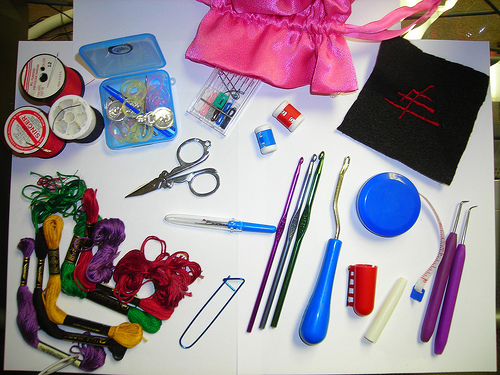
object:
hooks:
[420, 199, 478, 356]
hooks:
[246, 150, 326, 332]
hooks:
[297, 151, 351, 348]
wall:
[445, 77, 499, 114]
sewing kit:
[182, 60, 262, 140]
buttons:
[109, 92, 173, 142]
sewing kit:
[32, 13, 489, 361]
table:
[21, 32, 496, 317]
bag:
[336, 37, 491, 187]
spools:
[3, 50, 103, 162]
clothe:
[184, 2, 441, 95]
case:
[174, 55, 277, 144]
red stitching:
[390, 85, 438, 124]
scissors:
[127, 139, 222, 204]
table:
[459, 3, 498, 43]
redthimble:
[344, 262, 382, 314]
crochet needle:
[270, 151, 325, 328]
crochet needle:
[259, 153, 319, 328]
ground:
[405, 159, 444, 192]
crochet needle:
[252, 150, 319, 329]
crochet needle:
[241, 155, 305, 335]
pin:
[217, 67, 242, 102]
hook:
[299, 154, 351, 346]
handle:
[299, 238, 341, 344]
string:
[114, 230, 198, 317]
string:
[88, 215, 119, 283]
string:
[79, 187, 98, 289]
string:
[41, 212, 65, 325]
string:
[18, 237, 39, 340]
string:
[11, 173, 198, 373]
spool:
[48, 94, 105, 144]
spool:
[4, 106, 66, 158]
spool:
[19, 53, 85, 106]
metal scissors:
[123, 137, 221, 199]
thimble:
[346, 265, 377, 316]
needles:
[246, 149, 352, 344]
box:
[77, 33, 176, 150]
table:
[20, 5, 498, 373]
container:
[29, 31, 478, 372]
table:
[137, 81, 456, 364]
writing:
[375, 79, 448, 130]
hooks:
[255, 139, 301, 335]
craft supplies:
[17, 47, 490, 362]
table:
[21, 47, 483, 373]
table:
[79, 149, 456, 362]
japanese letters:
[385, 77, 450, 127]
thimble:
[341, 252, 384, 318]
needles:
[199, 97, 238, 130]